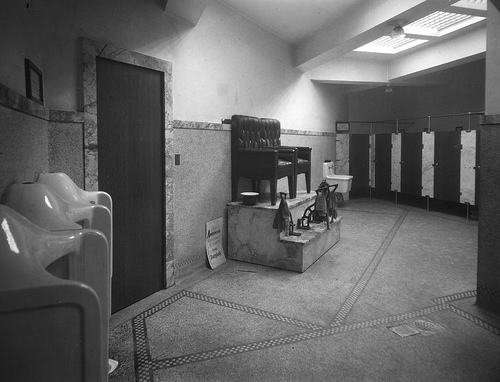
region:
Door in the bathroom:
[77, 36, 182, 311]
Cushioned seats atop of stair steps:
[225, 114, 312, 207]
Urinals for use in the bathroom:
[0, 169, 125, 378]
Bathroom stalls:
[332, 121, 482, 217]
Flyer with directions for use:
[202, 216, 225, 272]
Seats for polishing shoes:
[228, 110, 344, 268]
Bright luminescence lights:
[348, 0, 499, 60]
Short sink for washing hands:
[322, 153, 358, 196]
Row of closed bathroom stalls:
[333, 115, 480, 227]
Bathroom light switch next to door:
[172, 153, 182, 167]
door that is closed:
[90, 58, 179, 307]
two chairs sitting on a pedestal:
[226, 107, 318, 201]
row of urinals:
[7, 172, 142, 380]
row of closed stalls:
[346, 128, 481, 210]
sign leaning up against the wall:
[197, 214, 236, 269]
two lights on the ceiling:
[339, 9, 476, 98]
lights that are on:
[351, 1, 497, 70]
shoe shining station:
[214, 109, 357, 271]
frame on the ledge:
[22, 51, 57, 104]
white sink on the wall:
[319, 156, 359, 197]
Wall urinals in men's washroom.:
[2, 169, 120, 379]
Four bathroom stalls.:
[354, 116, 483, 213]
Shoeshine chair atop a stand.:
[231, 112, 313, 203]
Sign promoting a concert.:
[196, 213, 241, 273]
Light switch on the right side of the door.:
[175, 148, 182, 167]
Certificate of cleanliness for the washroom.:
[22, 56, 47, 106]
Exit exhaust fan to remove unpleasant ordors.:
[392, 32, 409, 42]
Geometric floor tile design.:
[157, 286, 463, 354]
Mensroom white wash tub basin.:
[322, 154, 355, 200]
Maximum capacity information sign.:
[332, 119, 352, 134]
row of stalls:
[340, 128, 475, 206]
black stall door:
[432, 136, 458, 198]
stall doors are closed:
[346, 132, 476, 203]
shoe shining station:
[218, 114, 353, 276]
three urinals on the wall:
[1, 169, 151, 380]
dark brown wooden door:
[96, 66, 179, 309]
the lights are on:
[348, 6, 468, 61]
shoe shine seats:
[259, 170, 308, 218]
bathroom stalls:
[457, 164, 465, 231]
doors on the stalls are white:
[467, 164, 490, 194]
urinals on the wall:
[34, 178, 76, 234]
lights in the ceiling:
[370, 25, 414, 62]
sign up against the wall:
[199, 223, 237, 261]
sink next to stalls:
[319, 165, 364, 187]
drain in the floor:
[411, 303, 443, 336]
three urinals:
[34, 156, 75, 246]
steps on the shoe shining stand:
[261, 201, 309, 268]